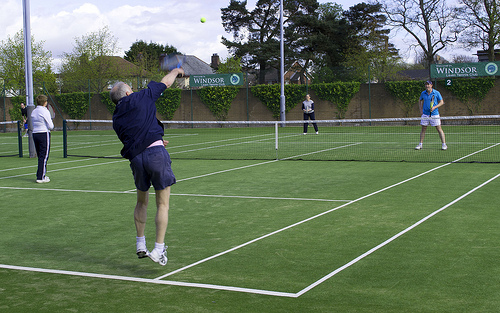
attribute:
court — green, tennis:
[0, 123, 499, 311]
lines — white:
[7, 126, 492, 304]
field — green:
[2, 118, 495, 309]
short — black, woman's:
[139, 152, 176, 187]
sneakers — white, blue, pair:
[132, 236, 169, 268]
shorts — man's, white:
[413, 114, 450, 127]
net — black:
[74, 125, 463, 162]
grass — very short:
[5, 116, 493, 311]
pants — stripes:
[31, 129, 68, 197]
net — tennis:
[56, 109, 498, 172]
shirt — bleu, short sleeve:
[418, 89, 440, 117]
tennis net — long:
[60, 123, 499, 163]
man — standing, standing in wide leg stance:
[413, 78, 448, 152]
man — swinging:
[109, 66, 186, 264]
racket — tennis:
[428, 98, 436, 115]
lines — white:
[61, 169, 430, 309]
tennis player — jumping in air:
[32, 65, 259, 308]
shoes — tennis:
[126, 201, 240, 310]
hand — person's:
[153, 54, 193, 94]